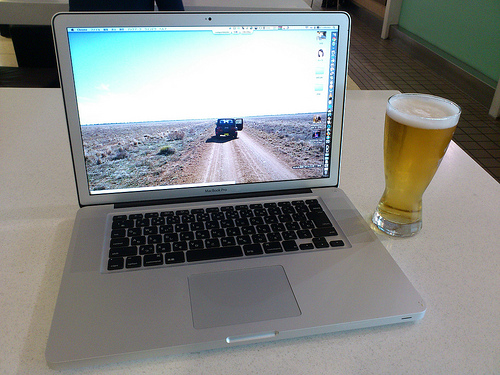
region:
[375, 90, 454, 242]
drinking glass next to laptop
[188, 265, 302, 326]
trackpad on the laptop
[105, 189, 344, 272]
black keys on the keyboard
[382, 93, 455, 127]
foam of the beer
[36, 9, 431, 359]
open silver laptop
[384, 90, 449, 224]
beer in the drinking glass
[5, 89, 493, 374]
white desk the laptop is on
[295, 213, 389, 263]
shadow of the drinking glass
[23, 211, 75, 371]
shadow of the laptop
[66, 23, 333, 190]
screen of the laptop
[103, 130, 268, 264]
this is a laptop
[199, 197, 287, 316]
this is a mac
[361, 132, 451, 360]
this is some beer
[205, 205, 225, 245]
this is a keyboard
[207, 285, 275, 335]
this is a trackpad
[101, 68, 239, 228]
the screen is on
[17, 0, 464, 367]
A laptop and a glass a beer on the side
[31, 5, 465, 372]
A laptop and a glass a beer on the side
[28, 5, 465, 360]
A laptop and a glass a beer on the side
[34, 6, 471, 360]
A laptop and a glass a beer on the side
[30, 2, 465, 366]
A laptop and a glass a beer on the side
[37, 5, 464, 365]
A laptop and a glass a beer on the side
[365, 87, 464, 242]
Full glass of beer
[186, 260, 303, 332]
Touch pad on laptop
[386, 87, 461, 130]
White foam head to beer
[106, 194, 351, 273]
Black plastic laptop keys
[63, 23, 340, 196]
Scene of truck on laptop screen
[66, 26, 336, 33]
Toolbar on laptop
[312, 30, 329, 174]
Icons on laptop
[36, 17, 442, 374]
Lit laptop screen with video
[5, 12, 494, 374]
Laptop and beer sitting on desk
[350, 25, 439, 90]
Edge of brown floor tiles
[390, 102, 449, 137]
White head on beer.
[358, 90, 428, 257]
Beer glass sitting on table.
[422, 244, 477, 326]
Table top is light gray.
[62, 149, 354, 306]
Laptop sitting on table.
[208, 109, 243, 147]
Jeep on path on laptop.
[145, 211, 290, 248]
Black buttons on laptop.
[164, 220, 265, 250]
White letters on keyboard.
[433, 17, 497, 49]
Green wall in room.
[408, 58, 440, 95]
Brown tiles on floor in room.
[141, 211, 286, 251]
keyboard is black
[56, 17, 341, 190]
a laptop screen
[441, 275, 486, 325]
a desk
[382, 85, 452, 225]
a glass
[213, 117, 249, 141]
a car on the screen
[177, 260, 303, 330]
Mouse pad on a laptop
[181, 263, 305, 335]
Mouse pad on a white laptop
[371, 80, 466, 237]
Glass of beer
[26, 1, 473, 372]
A laptop near a glass of beer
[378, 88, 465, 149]
Top of a glass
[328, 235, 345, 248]
Key on a keyboard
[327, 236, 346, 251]
Black key on a keyboard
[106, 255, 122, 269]
Key on a keyboard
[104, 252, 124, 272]
Black key on a keyboard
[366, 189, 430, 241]
Bottom of a glass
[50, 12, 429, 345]
a laptop near the beer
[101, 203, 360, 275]
keyboard of laptop under screen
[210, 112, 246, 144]
vehicle on screen on laptop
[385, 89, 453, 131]
foam head of beer in glass